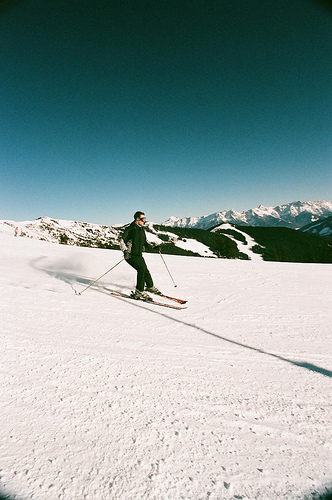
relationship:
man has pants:
[117, 211, 155, 302] [122, 252, 155, 292]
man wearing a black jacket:
[117, 211, 155, 302] [117, 221, 156, 257]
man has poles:
[117, 211, 155, 302] [159, 244, 186, 284]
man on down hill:
[117, 211, 155, 302] [3, 233, 330, 499]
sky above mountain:
[0, 0, 328, 222] [0, 214, 329, 260]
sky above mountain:
[0, 0, 328, 222] [297, 215, 330, 237]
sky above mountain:
[0, 0, 328, 222] [156, 198, 331, 229]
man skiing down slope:
[117, 211, 155, 302] [38, 249, 267, 383]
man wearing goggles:
[117, 211, 155, 302] [128, 208, 159, 225]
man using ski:
[117, 211, 155, 302] [110, 292, 187, 310]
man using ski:
[117, 211, 155, 302] [142, 286, 187, 304]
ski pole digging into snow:
[70, 250, 182, 288] [54, 299, 101, 315]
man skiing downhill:
[117, 211, 155, 302] [191, 260, 329, 499]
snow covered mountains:
[1, 231, 330, 498] [2, 215, 117, 248]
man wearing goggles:
[117, 211, 155, 302] [137, 216, 146, 221]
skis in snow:
[111, 279, 185, 310] [196, 271, 320, 320]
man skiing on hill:
[117, 211, 155, 302] [188, 257, 330, 499]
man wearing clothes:
[117, 211, 155, 302] [117, 222, 153, 292]